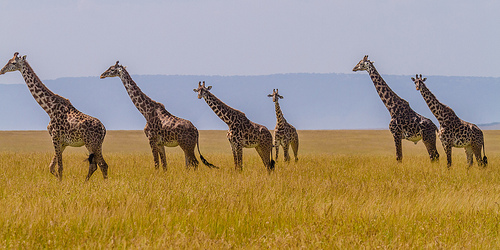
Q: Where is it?
A: This is at the field.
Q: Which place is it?
A: It is a field.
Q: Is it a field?
A: Yes, it is a field.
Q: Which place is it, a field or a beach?
A: It is a field.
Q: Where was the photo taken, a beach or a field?
A: It was taken at a field.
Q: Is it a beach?
A: No, it is a field.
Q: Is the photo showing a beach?
A: No, the picture is showing a field.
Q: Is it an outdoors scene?
A: Yes, it is outdoors.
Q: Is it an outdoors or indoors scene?
A: It is outdoors.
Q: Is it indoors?
A: No, it is outdoors.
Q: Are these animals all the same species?
A: Yes, all the animals are giraffes.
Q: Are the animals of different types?
A: No, all the animals are giraffes.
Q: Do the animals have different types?
A: No, all the animals are giraffes.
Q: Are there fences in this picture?
A: No, there are no fences.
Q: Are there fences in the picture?
A: No, there are no fences.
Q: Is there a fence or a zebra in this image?
A: No, there are no fences or zebras.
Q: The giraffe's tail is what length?
A: The tail is long.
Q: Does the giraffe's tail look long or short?
A: The tail is long.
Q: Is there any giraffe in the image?
A: Yes, there is a giraffe.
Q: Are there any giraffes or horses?
A: Yes, there is a giraffe.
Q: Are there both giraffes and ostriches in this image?
A: No, there is a giraffe but no ostriches.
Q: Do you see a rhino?
A: No, there are no rhinos.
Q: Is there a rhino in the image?
A: No, there are no rhinos.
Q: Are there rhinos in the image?
A: No, there are no rhinos.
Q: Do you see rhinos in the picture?
A: No, there are no rhinos.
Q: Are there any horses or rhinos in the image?
A: No, there are no rhinos or horses.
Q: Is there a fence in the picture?
A: No, there are no fences.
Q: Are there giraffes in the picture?
A: Yes, there is a giraffe.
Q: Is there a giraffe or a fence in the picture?
A: Yes, there is a giraffe.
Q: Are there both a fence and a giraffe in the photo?
A: No, there is a giraffe but no fences.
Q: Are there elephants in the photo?
A: No, there are no elephants.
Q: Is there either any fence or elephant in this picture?
A: No, there are no elephants or fences.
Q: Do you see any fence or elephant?
A: No, there are no elephants or fences.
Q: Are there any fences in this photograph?
A: No, there are no fences.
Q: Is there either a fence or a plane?
A: No, there are no fences or airplanes.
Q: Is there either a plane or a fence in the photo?
A: No, there are no fences or airplanes.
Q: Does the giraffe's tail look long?
A: Yes, the tail is long.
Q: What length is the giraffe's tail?
A: The tail is long.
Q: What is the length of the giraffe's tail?
A: The tail is long.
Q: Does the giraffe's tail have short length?
A: No, the tail is long.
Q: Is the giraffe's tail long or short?
A: The tail is long.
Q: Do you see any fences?
A: No, there are no fences.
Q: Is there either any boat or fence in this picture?
A: No, there are no fences or boats.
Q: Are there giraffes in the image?
A: Yes, there is a giraffe.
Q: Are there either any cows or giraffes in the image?
A: Yes, there is a giraffe.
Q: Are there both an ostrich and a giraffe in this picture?
A: No, there is a giraffe but no ostriches.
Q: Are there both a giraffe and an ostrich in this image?
A: No, there is a giraffe but no ostriches.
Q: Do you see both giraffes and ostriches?
A: No, there is a giraffe but no ostriches.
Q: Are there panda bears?
A: No, there are no panda bears.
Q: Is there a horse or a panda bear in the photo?
A: No, there are no pandas or horses.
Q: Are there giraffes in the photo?
A: Yes, there is a giraffe.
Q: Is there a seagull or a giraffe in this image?
A: Yes, there is a giraffe.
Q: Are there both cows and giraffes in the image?
A: No, there is a giraffe but no cows.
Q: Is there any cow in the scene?
A: No, there are no cows.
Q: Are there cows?
A: No, there are no cows.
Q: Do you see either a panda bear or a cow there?
A: No, there are no cows or pandas.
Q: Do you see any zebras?
A: No, there are no zebras.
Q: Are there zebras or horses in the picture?
A: No, there are no zebras or horses.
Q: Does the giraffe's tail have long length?
A: Yes, the tail is long.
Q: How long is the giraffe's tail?
A: The tail is long.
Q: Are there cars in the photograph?
A: No, there are no cars.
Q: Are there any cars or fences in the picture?
A: No, there are no cars or fences.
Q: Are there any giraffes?
A: Yes, there is a giraffe.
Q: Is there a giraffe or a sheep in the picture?
A: Yes, there is a giraffe.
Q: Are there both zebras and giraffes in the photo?
A: No, there is a giraffe but no zebras.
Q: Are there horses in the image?
A: No, there are no horses.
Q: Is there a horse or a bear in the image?
A: No, there are no horses or bears.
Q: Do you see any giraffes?
A: Yes, there is a giraffe.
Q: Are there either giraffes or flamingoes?
A: Yes, there is a giraffe.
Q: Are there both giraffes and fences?
A: No, there is a giraffe but no fences.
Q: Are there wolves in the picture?
A: No, there are no wolves.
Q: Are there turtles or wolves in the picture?
A: No, there are no wolves or turtles.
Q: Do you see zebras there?
A: No, there are no zebras.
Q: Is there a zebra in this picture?
A: No, there are no zebras.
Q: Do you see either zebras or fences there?
A: No, there are no zebras or fences.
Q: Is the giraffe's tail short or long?
A: The tail is long.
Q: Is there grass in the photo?
A: Yes, there is grass.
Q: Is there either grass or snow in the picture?
A: Yes, there is grass.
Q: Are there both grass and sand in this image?
A: No, there is grass but no sand.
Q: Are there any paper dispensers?
A: No, there are no paper dispensers.